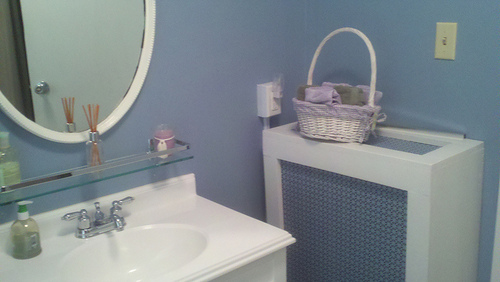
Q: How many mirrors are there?
A: One.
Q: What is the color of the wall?
A: Blue.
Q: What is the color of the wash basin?
A: White.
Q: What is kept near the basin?
A: Hand wash.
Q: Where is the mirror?
A: In the wall.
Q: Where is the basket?
A: In the table.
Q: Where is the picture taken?
A: In the bathroom.